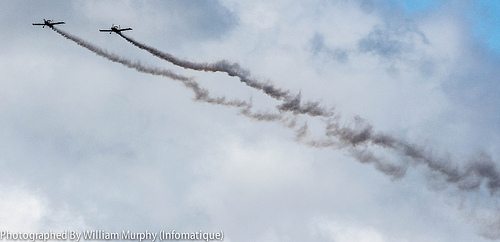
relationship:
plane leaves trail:
[99, 21, 136, 42] [127, 34, 235, 64]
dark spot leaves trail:
[0, 0, 55, 23] [51, 33, 109, 58]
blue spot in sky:
[400, 1, 499, 43] [5, 8, 474, 238]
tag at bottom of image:
[0, 226, 227, 241] [0, 0, 498, 240]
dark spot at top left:
[0, 0, 90, 53] [0, 0, 166, 130]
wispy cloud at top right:
[356, 8, 428, 81] [321, 1, 498, 118]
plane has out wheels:
[99, 21, 136, 42] [107, 32, 123, 35]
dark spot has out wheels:
[0, 0, 55, 23] [41, 25, 60, 29]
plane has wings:
[99, 21, 136, 42] [98, 27, 134, 33]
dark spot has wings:
[0, 0, 55, 23] [33, 21, 69, 27]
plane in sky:
[99, 21, 136, 42] [5, 8, 474, 238]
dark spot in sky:
[0, 0, 55, 23] [5, 8, 474, 238]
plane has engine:
[99, 21, 136, 42] [113, 26, 118, 30]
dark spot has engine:
[0, 0, 55, 23] [44, 19, 48, 23]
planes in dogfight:
[31, 17, 134, 38] [23, 10, 183, 79]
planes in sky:
[31, 17, 134, 38] [5, 8, 474, 238]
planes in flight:
[31, 17, 134, 38] [23, 10, 183, 79]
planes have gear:
[31, 17, 134, 38] [34, 27, 123, 32]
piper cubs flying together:
[31, 17, 134, 38] [16, 11, 152, 57]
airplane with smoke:
[99, 21, 136, 42] [102, 40, 270, 108]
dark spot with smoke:
[0, 0, 55, 23] [102, 40, 270, 108]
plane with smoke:
[99, 21, 136, 42] [102, 40, 270, 108]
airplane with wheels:
[99, 21, 136, 42] [107, 32, 123, 35]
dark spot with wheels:
[0, 0, 55, 23] [41, 25, 60, 29]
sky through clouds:
[400, 1, 499, 43] [5, 8, 474, 238]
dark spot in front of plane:
[0, 0, 55, 23] [99, 21, 136, 42]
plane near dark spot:
[99, 21, 136, 42] [0, 0, 55, 23]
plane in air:
[99, 21, 136, 42] [22, 13, 213, 116]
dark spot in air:
[0, 0, 55, 23] [22, 13, 213, 116]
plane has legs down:
[99, 21, 136, 42] [109, 30, 123, 35]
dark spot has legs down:
[0, 0, 55, 23] [42, 23, 58, 29]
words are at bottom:
[0, 226, 227, 241] [0, 201, 499, 241]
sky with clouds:
[5, 8, 474, 238] [5, 8, 474, 238]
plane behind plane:
[99, 21, 136, 42] [92, 13, 138, 49]